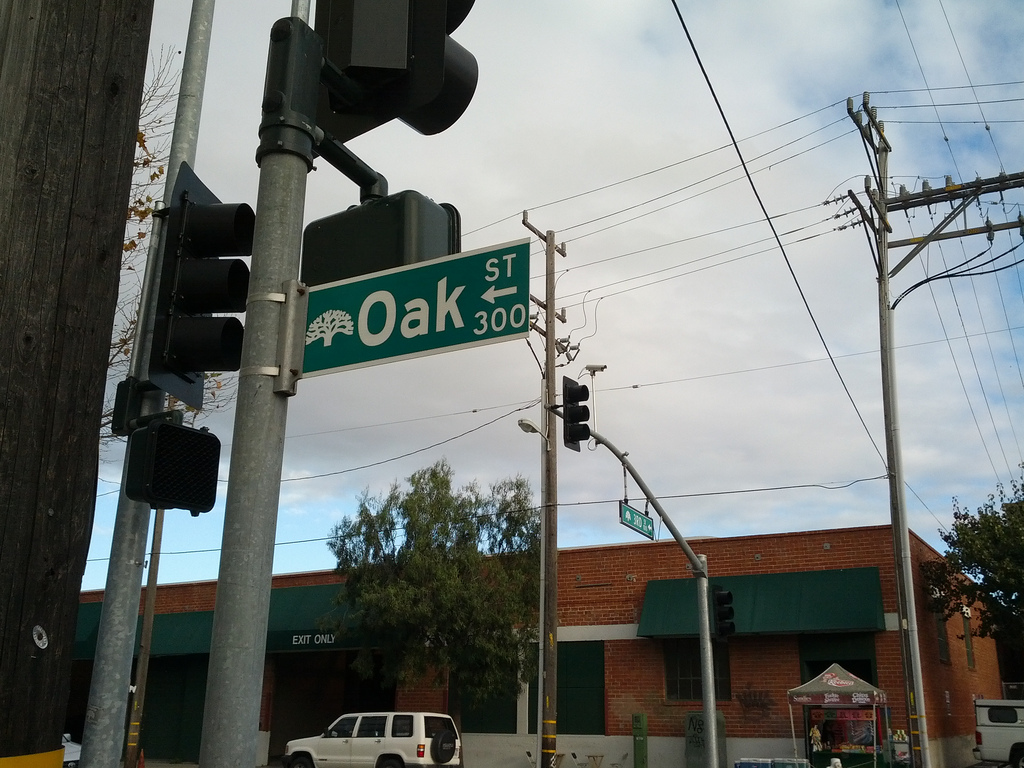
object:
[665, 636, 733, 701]
window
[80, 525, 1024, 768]
building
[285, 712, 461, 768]
suv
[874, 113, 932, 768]
pole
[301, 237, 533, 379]
sign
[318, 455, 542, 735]
tree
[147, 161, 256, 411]
signal